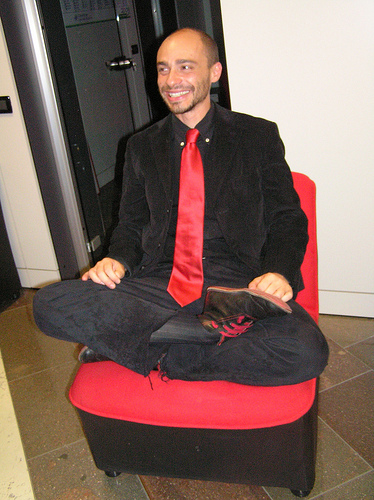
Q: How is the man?
A: Happy.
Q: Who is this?
A: Man.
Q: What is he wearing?
A: Tie.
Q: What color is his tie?
A: Red.